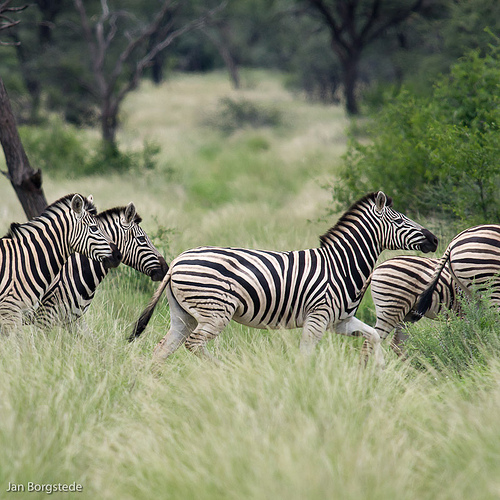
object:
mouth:
[413, 239, 439, 253]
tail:
[126, 259, 176, 341]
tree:
[13, 0, 230, 177]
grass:
[0, 68, 499, 499]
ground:
[1, 70, 498, 498]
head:
[367, 189, 438, 255]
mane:
[95, 205, 142, 222]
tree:
[310, 27, 480, 227]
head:
[69, 190, 123, 270]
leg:
[183, 302, 235, 367]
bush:
[203, 89, 294, 156]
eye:
[391, 214, 403, 229]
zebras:
[1, 193, 123, 337]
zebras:
[126, 191, 438, 372]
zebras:
[0, 202, 172, 334]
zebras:
[357, 256, 476, 368]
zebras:
[403, 223, 500, 324]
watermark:
[2, 481, 84, 494]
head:
[110, 202, 173, 280]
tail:
[403, 243, 456, 325]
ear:
[370, 189, 387, 215]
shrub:
[310, 28, 500, 246]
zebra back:
[444, 228, 482, 286]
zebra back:
[371, 267, 394, 304]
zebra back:
[164, 256, 196, 303]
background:
[0, 0, 500, 499]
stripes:
[229, 246, 281, 324]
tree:
[263, 0, 448, 118]